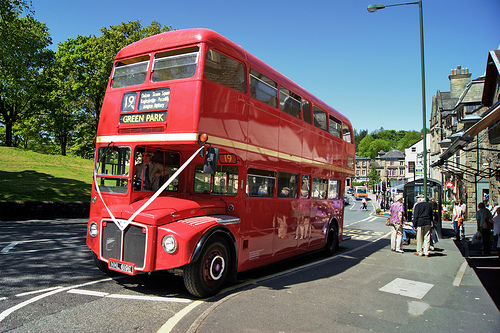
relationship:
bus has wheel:
[85, 28, 356, 298] [183, 235, 229, 296]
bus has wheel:
[85, 28, 356, 298] [326, 224, 338, 257]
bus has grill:
[85, 28, 356, 298] [101, 222, 147, 268]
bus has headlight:
[85, 28, 356, 298] [161, 235, 178, 254]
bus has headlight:
[85, 28, 356, 298] [91, 222, 100, 238]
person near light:
[388, 195, 404, 251] [367, 0, 427, 201]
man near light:
[412, 195, 432, 256] [367, 0, 427, 201]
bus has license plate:
[85, 28, 356, 298] [107, 257, 135, 275]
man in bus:
[286, 95, 300, 122] [85, 28, 356, 298]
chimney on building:
[448, 67, 471, 98] [430, 92, 461, 182]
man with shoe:
[412, 195, 432, 256] [412, 251, 423, 256]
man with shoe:
[412, 195, 432, 256] [425, 253, 430, 257]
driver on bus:
[127, 151, 172, 190] [85, 28, 356, 298]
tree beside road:
[0, 17, 57, 146] [0, 186, 393, 332]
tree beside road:
[51, 36, 119, 121] [0, 186, 393, 332]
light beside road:
[367, 0, 427, 201] [0, 186, 393, 332]